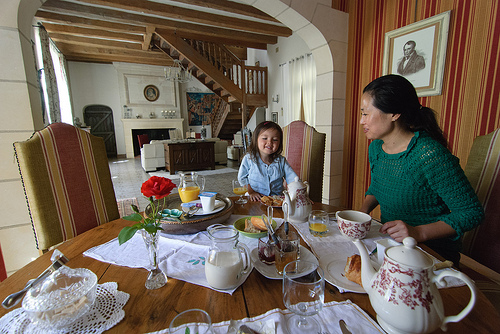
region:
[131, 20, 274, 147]
wood stair case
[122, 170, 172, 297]
red flower in a vase on table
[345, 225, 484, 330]
white porcelain tea kettle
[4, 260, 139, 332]
white doily under glass dish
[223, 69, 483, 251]
woman and child sitting at table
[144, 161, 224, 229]
tray with a pitcher of orange juice on it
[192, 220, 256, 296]
glass jar with cream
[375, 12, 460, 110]
picture of man on the wall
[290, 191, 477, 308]
dishes sitting on a white place matt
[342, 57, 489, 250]
woman wearing a green knitted shirt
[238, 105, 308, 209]
young girl at the table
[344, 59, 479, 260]
older woman at the table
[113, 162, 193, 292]
a red rose on the table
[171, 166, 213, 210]
a pitcher of orange juice on the table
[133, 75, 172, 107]
a circular painting on the wall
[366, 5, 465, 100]
a square painting on the wall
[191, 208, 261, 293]
a pitcher of milk on the table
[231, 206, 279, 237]
a bowl with an orange on the table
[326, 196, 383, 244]
soup bowl in front of the old woman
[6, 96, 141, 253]
a chair with no one sitting in it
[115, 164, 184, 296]
Red rose in vase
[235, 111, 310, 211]
Young girl in blue shirt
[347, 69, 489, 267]
Woman in green shirt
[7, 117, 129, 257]
Striped dinner chair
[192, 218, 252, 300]
Pitcher of milk on table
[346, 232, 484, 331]
Tea pot on table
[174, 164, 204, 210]
Pitcher of orange juice on table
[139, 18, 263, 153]
Staircase in the background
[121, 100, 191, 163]
Fireplace in the background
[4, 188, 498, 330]
Dinning room table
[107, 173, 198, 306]
a red flower in a glass vase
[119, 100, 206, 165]
a white fire place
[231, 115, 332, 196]
a little girl having breakfast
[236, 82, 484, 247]
a little girl and her mother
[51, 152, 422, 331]
a breakfast spread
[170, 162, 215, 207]
orange juice in a glass pitcher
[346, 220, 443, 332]
a red and white tea pot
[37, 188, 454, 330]
a wooden table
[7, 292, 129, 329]
a white lace doily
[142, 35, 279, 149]
a wooden staircase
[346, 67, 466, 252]
A woman wearing a green sweatshirt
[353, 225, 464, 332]
White and pink tea pot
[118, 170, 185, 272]
Red rose in a vase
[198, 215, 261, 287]
Clear cup with white liquid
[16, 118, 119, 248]
Brown, red and yellow chair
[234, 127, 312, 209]
Girl with blue shirt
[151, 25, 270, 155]
The stairs are wood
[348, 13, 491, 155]
The wall is striped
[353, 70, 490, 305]
The woman is sitting down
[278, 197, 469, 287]
The place mats are white